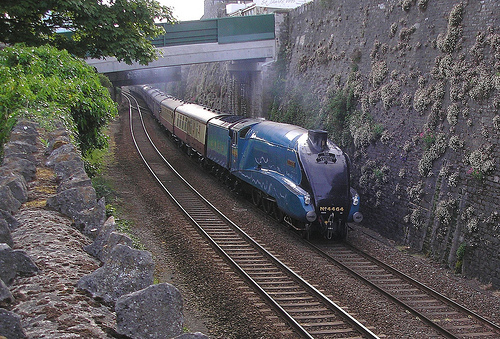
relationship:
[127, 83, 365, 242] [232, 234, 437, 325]
cars on tracks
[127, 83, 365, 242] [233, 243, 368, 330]
cars going tracks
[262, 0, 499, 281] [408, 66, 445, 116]
rocks has moss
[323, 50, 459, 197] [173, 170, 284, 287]
rocks on tracks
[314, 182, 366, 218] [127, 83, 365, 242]
lights on cars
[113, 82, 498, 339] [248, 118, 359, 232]
rails crossing shaft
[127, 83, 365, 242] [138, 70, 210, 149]
cars with cars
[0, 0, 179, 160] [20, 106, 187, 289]
bushes growing side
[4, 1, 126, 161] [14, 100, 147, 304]
bushes on ledge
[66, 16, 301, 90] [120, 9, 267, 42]
bridge with roof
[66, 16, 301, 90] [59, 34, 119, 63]
bridge with windows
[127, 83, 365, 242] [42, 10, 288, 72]
cars under bridge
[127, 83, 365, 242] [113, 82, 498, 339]
cars on rails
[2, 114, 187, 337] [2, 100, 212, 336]
ledge on ledge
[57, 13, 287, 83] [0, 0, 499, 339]
tunnel over canyon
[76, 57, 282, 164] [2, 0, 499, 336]
tunnel between cliffs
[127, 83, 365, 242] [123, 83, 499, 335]
cars on rails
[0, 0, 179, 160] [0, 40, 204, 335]
bushes on top of ledge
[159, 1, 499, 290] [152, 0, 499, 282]
plants growing on side of cliff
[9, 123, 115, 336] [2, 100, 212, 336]
path on ledge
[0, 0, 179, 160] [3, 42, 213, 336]
bushes growing by side of cliff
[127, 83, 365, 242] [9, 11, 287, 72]
cars traveling under tunnel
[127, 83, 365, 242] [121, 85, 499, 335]
cars moving down track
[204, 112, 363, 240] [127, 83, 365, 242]
engine on cars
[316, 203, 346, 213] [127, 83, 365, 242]
number on cars